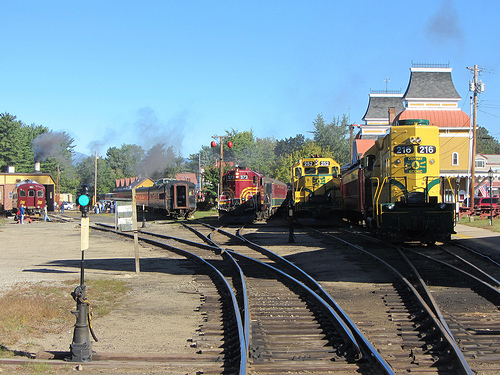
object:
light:
[227, 141, 233, 148]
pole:
[219, 136, 225, 194]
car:
[216, 166, 288, 225]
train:
[288, 153, 348, 225]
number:
[396, 146, 402, 154]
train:
[338, 117, 457, 247]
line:
[467, 104, 500, 120]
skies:
[0, 0, 500, 161]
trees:
[271, 140, 342, 190]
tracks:
[22, 215, 249, 374]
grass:
[0, 278, 134, 375]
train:
[217, 165, 290, 225]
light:
[76, 192, 92, 208]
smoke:
[31, 104, 195, 183]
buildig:
[390, 60, 480, 221]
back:
[377, 117, 455, 248]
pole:
[470, 63, 480, 218]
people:
[19, 204, 25, 224]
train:
[10, 180, 47, 223]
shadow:
[22, 188, 499, 288]